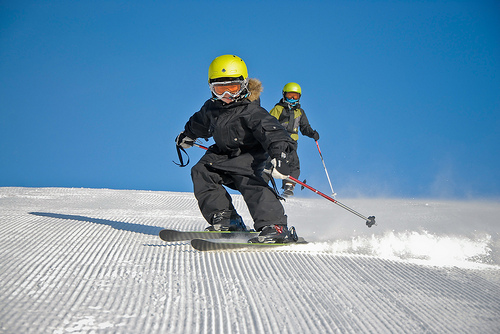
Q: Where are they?
A: Mountain.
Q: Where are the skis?
A: On the snow.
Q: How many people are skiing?
A: Two.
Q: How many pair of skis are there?
A: Two.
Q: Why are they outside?
A: Skiing.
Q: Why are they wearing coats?
A: Cold.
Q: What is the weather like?
A: Cold.